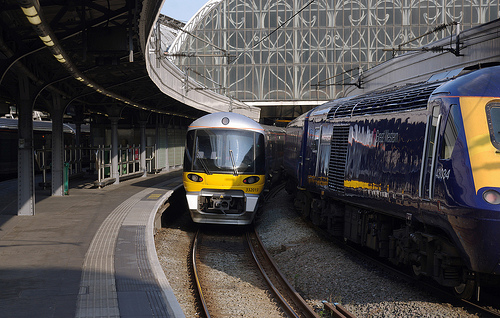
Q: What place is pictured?
A: It is a station.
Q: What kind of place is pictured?
A: It is a station.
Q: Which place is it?
A: It is a station.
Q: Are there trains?
A: Yes, there is a train.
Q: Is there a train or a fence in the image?
A: Yes, there is a train.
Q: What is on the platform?
A: The train is on the platform.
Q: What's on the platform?
A: The train is on the platform.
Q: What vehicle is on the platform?
A: The vehicle is a train.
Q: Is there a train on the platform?
A: Yes, there is a train on the platform.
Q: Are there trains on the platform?
A: Yes, there is a train on the platform.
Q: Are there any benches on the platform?
A: No, there is a train on the platform.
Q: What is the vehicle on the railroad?
A: The vehicle is a train.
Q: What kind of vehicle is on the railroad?
A: The vehicle is a train.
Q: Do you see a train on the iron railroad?
A: Yes, there is a train on the railroad.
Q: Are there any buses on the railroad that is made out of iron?
A: No, there is a train on the railroad.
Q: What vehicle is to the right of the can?
A: The vehicle is a train.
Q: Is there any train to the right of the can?
A: Yes, there is a train to the right of the can.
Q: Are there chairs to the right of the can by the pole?
A: No, there is a train to the right of the can.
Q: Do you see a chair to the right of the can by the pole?
A: No, there is a train to the right of the can.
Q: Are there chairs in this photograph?
A: No, there are no chairs.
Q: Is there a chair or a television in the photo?
A: No, there are no chairs or televisions.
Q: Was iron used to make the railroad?
A: Yes, the railroad is made of iron.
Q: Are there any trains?
A: Yes, there are trains.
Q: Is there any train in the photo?
A: Yes, there are trains.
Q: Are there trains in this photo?
A: Yes, there are trains.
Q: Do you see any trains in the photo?
A: Yes, there are trains.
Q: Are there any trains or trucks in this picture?
A: Yes, there are trains.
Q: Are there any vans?
A: No, there are no vans.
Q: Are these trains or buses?
A: These are trains.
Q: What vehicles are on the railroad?
A: The vehicles are trains.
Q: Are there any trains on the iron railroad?
A: Yes, there are trains on the railroad.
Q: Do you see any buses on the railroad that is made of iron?
A: No, there are trains on the railroad.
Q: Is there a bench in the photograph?
A: No, there are no benches.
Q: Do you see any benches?
A: No, there are no benches.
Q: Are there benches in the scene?
A: No, there are no benches.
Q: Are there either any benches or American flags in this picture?
A: No, there are no benches or American flags.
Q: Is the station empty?
A: Yes, the station is empty.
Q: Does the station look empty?
A: Yes, the station is empty.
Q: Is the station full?
A: No, the station is empty.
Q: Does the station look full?
A: No, the station is empty.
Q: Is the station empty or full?
A: The station is empty.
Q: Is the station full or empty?
A: The station is empty.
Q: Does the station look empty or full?
A: The station is empty.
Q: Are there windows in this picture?
A: Yes, there is a window.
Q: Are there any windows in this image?
A: Yes, there is a window.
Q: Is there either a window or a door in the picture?
A: Yes, there is a window.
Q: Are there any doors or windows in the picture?
A: Yes, there is a window.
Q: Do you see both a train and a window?
A: Yes, there are both a window and a train.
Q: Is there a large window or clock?
A: Yes, there is a large window.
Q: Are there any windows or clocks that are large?
A: Yes, the window is large.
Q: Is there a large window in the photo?
A: Yes, there is a large window.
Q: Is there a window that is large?
A: Yes, there is a window that is large.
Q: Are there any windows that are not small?
A: Yes, there is a large window.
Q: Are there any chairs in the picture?
A: No, there are no chairs.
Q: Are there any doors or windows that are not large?
A: No, there is a window but it is large.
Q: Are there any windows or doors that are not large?
A: No, there is a window but it is large.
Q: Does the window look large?
A: Yes, the window is large.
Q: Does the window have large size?
A: Yes, the window is large.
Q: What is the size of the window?
A: The window is large.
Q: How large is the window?
A: The window is large.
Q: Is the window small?
A: No, the window is large.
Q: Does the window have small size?
A: No, the window is large.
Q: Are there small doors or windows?
A: No, there is a window but it is large.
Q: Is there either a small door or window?
A: No, there is a window but it is large.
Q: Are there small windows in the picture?
A: No, there is a window but it is large.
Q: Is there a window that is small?
A: No, there is a window but it is large.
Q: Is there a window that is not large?
A: No, there is a window but it is large.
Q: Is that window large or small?
A: The window is large.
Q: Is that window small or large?
A: The window is large.